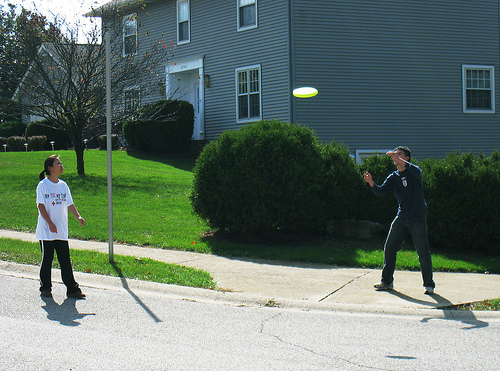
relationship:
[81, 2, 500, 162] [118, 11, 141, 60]
house has window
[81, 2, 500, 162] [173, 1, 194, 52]
house has window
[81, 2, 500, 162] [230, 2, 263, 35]
house has window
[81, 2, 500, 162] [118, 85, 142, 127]
house has window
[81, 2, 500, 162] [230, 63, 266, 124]
house has window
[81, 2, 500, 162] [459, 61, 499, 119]
house has window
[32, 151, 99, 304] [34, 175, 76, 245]
girl wears shirt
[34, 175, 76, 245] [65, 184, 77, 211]
shirt has sleeve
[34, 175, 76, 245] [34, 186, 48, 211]
shirt has sleeve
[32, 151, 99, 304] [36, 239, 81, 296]
girl wears pants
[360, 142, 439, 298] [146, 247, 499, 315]
boy on sidewalk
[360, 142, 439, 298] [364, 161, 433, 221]
boy wears shirt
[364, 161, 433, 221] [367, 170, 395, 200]
shirt has sleeve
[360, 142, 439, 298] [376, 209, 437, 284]
boy wears pants